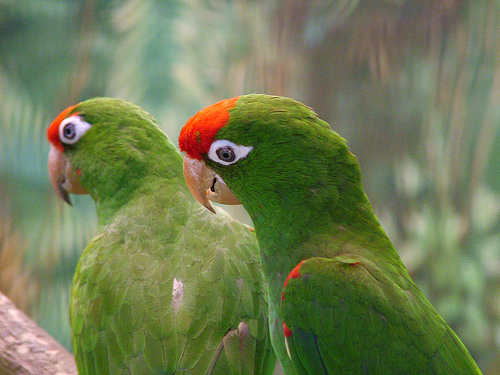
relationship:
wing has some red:
[280, 252, 449, 374] [282, 257, 363, 336]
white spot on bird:
[173, 277, 183, 313] [45, 95, 275, 374]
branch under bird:
[0, 292, 75, 373] [45, 95, 275, 374]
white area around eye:
[207, 139, 254, 166] [215, 146, 235, 162]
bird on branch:
[178, 94, 482, 373] [0, 292, 75, 373]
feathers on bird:
[179, 93, 482, 374] [178, 94, 482, 373]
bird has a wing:
[178, 94, 482, 373] [280, 252, 449, 374]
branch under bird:
[0, 292, 75, 373] [178, 94, 482, 373]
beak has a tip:
[183, 156, 243, 214] [205, 202, 217, 214]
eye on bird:
[215, 146, 235, 162] [178, 94, 482, 373]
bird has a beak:
[178, 94, 482, 373] [183, 156, 243, 214]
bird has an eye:
[178, 94, 482, 373] [215, 146, 235, 162]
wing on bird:
[280, 252, 449, 374] [178, 94, 482, 373]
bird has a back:
[45, 95, 275, 374] [70, 189, 275, 373]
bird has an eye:
[45, 95, 275, 374] [63, 123, 74, 138]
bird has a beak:
[45, 95, 275, 374] [49, 143, 89, 205]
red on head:
[46, 101, 81, 154] [46, 96, 183, 226]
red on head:
[282, 257, 363, 336] [46, 96, 183, 226]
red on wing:
[282, 257, 363, 336] [280, 252, 449, 374]